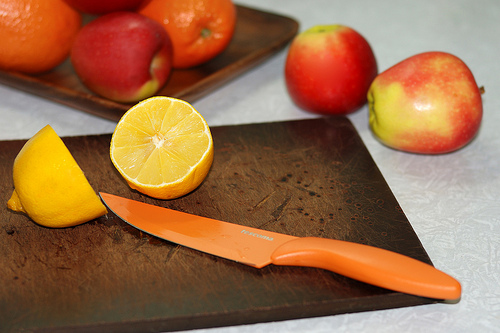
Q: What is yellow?
A: Lemon.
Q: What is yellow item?
A: Lemon.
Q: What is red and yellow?
A: Apple.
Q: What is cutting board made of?
A: Wood.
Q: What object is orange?
A: Knife.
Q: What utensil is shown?
A: A knife.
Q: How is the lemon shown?
A: Cut in half.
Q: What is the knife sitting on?
A: A cutting board.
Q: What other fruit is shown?
A: Apples.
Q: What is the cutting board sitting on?
A: A counter.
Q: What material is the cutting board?
A: Wood.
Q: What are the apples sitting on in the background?
A: A tray.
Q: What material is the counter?
A: Marble.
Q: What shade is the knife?
A: Orange.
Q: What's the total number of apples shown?
A: 3.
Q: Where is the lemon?
A: On the cutting board.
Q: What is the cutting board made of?
A: Wood.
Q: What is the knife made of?
A: Plastic.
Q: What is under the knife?
A: A cutting board.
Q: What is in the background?
A: Fruit.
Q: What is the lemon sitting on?
A: A cutting board.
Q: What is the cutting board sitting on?
A: A white table.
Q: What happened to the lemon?
A: It was cut in half.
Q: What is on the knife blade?
A: A logo.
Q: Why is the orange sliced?
A: To be eaten.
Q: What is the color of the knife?
A: Orange.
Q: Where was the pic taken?
A: In the kitchen.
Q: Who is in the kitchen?
A: No one.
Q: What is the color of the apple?
A: Red.